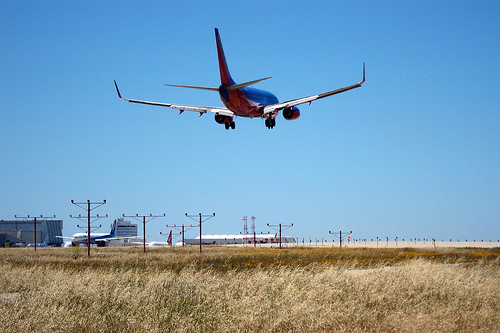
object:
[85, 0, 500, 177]
clouds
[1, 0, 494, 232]
blue sky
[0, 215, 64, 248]
building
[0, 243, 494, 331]
ground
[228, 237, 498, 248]
fence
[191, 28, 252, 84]
tail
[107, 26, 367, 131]
plane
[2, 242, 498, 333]
grass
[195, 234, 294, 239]
clouds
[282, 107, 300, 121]
jet engine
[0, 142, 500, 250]
background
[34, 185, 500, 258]
posts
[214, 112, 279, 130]
landing gear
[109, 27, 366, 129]
airplane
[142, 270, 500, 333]
area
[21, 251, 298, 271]
landing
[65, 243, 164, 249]
plane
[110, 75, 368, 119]
wing